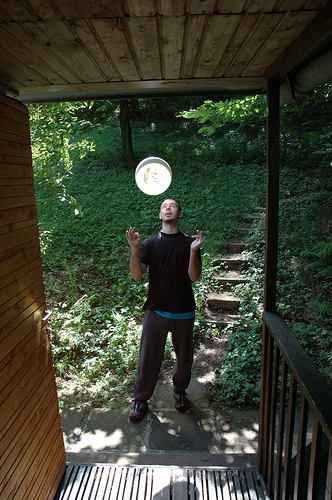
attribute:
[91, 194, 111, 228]
foliage — Green 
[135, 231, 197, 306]
t shirt — navy blue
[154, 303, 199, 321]
blue shirt — light blue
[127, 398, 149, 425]
shoe — Black, Red, Gray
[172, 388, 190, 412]
shoe — Black, Red, Gray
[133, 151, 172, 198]
frisbee — White 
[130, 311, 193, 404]
sweatpants — comfortable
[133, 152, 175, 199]
pan — round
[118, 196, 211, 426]
man — standing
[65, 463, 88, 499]
slats — wooden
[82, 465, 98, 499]
slats — wooden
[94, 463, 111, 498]
slats — wooden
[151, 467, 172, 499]
slats — wooden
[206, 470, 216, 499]
slats — wooden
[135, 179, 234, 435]
man — looking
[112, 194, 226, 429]
man — blue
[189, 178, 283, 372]
stairs — concrete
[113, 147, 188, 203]
pan — round, metal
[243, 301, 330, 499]
fence — wooden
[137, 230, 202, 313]
shirt — black, dark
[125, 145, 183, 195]
ball — White 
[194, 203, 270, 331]
slates — Wooden 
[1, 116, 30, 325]
pine siding — Light 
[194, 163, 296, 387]
pathway steps — Brown 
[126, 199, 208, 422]
man — throwing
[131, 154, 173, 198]
pan — flying